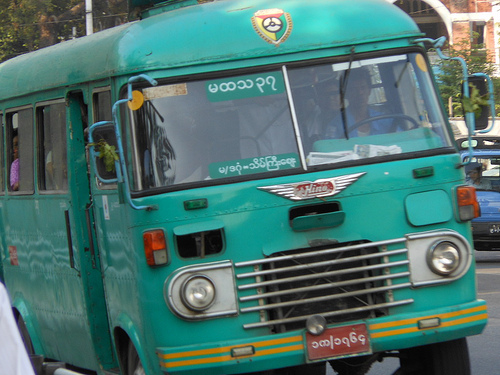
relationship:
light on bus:
[440, 185, 487, 221] [5, 0, 495, 343]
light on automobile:
[183, 196, 211, 213] [0, 0, 488, 375]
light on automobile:
[227, 344, 257, 357] [0, 0, 488, 375]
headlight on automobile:
[179, 274, 215, 312] [0, 0, 488, 375]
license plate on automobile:
[301, 317, 374, 364] [0, 0, 488, 375]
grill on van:
[227, 241, 419, 332] [71, 75, 471, 306]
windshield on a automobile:
[117, 45, 471, 182] [0, 0, 488, 375]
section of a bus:
[91, 133, 327, 363] [19, 23, 474, 372]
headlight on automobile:
[427, 239, 462, 276] [0, 0, 488, 375]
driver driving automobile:
[324, 66, 404, 138] [0, 0, 488, 375]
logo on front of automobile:
[249, 7, 294, 48] [4, 2, 488, 369]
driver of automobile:
[320, 39, 427, 173] [0, 0, 488, 375]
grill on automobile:
[233, 237, 413, 330] [0, 0, 488, 375]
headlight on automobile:
[427, 235, 462, 276] [0, 0, 488, 375]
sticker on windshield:
[202, 150, 304, 180] [120, 42, 459, 194]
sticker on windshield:
[200, 67, 287, 109] [120, 42, 459, 194]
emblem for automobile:
[272, 170, 369, 210] [0, 0, 488, 375]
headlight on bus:
[427, 239, 462, 276] [69, 33, 486, 354]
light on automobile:
[306, 313, 328, 336] [0, 0, 488, 375]